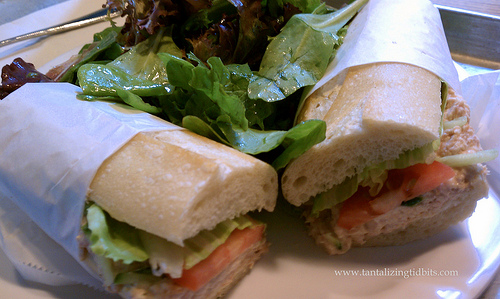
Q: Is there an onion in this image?
A: Yes, there is an onion.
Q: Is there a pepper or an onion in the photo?
A: Yes, there is an onion.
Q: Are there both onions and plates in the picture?
A: Yes, there are both an onion and a plate.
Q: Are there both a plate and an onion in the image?
A: Yes, there are both an onion and a plate.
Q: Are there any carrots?
A: No, there are no carrots.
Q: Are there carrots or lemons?
A: No, there are no carrots or lemons.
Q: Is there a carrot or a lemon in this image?
A: No, there are no carrots or lemons.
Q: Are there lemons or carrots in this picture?
A: No, there are no carrots or lemons.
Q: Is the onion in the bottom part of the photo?
A: Yes, the onion is in the bottom of the image.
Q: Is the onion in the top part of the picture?
A: No, the onion is in the bottom of the image.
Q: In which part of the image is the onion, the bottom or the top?
A: The onion is in the bottom of the image.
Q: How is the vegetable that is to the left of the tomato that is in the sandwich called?
A: The vegetable is an onion.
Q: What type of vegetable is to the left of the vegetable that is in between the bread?
A: The vegetable is an onion.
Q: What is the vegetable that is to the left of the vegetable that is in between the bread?
A: The vegetable is an onion.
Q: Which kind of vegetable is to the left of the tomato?
A: The vegetable is an onion.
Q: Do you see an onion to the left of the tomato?
A: Yes, there is an onion to the left of the tomato.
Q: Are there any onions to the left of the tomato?
A: Yes, there is an onion to the left of the tomato.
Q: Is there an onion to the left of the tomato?
A: Yes, there is an onion to the left of the tomato.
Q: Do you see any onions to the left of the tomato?
A: Yes, there is an onion to the left of the tomato.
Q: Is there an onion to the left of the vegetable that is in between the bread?
A: Yes, there is an onion to the left of the tomato.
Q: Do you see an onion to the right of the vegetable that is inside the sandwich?
A: No, the onion is to the left of the tomato.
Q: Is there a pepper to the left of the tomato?
A: No, there is an onion to the left of the tomato.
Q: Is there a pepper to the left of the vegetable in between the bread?
A: No, there is an onion to the left of the tomato.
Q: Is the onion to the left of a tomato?
A: Yes, the onion is to the left of a tomato.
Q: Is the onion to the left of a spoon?
A: No, the onion is to the left of a tomato.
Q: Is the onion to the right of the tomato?
A: No, the onion is to the left of the tomato.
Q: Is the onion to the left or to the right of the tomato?
A: The onion is to the left of the tomato.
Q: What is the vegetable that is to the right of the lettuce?
A: The vegetable is an onion.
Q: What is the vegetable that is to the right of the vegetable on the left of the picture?
A: The vegetable is an onion.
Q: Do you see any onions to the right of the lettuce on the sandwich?
A: Yes, there is an onion to the right of the lettuce.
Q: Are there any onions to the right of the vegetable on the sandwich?
A: Yes, there is an onion to the right of the lettuce.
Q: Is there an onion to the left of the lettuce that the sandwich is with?
A: No, the onion is to the right of the lettuce.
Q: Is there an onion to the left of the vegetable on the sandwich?
A: No, the onion is to the right of the lettuce.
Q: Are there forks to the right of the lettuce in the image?
A: No, there is an onion to the right of the lettuce.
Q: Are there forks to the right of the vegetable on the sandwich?
A: No, there is an onion to the right of the lettuce.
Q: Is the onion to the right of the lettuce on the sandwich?
A: Yes, the onion is to the right of the lettuce.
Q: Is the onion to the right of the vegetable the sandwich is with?
A: Yes, the onion is to the right of the lettuce.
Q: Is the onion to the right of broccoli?
A: No, the onion is to the right of the lettuce.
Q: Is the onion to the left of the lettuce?
A: No, the onion is to the right of the lettuce.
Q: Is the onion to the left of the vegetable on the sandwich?
A: No, the onion is to the right of the lettuce.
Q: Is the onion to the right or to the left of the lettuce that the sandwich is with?
A: The onion is to the right of the lettuce.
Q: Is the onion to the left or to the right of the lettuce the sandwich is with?
A: The onion is to the right of the lettuce.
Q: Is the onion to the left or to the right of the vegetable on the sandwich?
A: The onion is to the right of the lettuce.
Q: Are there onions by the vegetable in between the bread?
A: Yes, there is an onion by the tomato.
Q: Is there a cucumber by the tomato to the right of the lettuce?
A: No, there is an onion by the tomato.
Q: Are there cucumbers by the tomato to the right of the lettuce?
A: No, there is an onion by the tomato.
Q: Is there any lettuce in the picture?
A: Yes, there is lettuce.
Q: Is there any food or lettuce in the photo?
A: Yes, there is lettuce.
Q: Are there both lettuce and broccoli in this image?
A: No, there is lettuce but no broccoli.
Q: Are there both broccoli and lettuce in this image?
A: No, there is lettuce but no broccoli.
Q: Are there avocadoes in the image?
A: No, there are no avocadoes.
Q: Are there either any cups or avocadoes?
A: No, there are no avocadoes or cups.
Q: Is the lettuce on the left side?
A: Yes, the lettuce is on the left of the image.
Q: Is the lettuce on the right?
A: No, the lettuce is on the left of the image.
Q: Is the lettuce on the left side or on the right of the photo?
A: The lettuce is on the left of the image.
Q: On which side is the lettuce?
A: The lettuce is on the left of the image.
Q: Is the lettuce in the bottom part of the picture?
A: Yes, the lettuce is in the bottom of the image.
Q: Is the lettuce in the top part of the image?
A: No, the lettuce is in the bottom of the image.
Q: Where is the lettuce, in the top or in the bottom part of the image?
A: The lettuce is in the bottom of the image.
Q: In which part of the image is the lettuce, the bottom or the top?
A: The lettuce is in the bottom of the image.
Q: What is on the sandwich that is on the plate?
A: The lettuce is on the sandwich.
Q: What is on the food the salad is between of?
A: The lettuce is on the sandwich.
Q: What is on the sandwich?
A: The lettuce is on the sandwich.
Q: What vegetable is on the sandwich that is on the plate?
A: The vegetable is lettuce.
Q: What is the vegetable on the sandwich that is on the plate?
A: The vegetable is lettuce.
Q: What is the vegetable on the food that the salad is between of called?
A: The vegetable is lettuce.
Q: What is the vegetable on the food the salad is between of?
A: The vegetable is lettuce.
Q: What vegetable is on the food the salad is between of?
A: The vegetable is lettuce.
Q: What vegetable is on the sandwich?
A: The vegetable is lettuce.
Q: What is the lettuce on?
A: The lettuce is on the sandwich.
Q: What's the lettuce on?
A: The lettuce is on the sandwich.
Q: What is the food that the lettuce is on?
A: The food is a sandwich.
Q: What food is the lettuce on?
A: The lettuce is on the sandwich.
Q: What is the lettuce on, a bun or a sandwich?
A: The lettuce is on a sandwich.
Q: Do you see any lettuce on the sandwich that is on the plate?
A: Yes, there is lettuce on the sandwich.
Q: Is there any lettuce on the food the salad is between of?
A: Yes, there is lettuce on the sandwich.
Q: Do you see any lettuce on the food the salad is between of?
A: Yes, there is lettuce on the sandwich.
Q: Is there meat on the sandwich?
A: No, there is lettuce on the sandwich.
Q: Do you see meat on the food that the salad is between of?
A: No, there is lettuce on the sandwich.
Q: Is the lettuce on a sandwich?
A: Yes, the lettuce is on a sandwich.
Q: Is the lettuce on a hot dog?
A: No, the lettuce is on a sandwich.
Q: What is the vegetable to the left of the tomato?
A: The vegetable is lettuce.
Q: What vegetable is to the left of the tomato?
A: The vegetable is lettuce.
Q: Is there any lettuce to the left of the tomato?
A: Yes, there is lettuce to the left of the tomato.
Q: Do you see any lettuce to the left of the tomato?
A: Yes, there is lettuce to the left of the tomato.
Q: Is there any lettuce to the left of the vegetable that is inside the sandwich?
A: Yes, there is lettuce to the left of the tomato.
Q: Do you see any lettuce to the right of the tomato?
A: No, the lettuce is to the left of the tomato.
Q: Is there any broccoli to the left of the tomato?
A: No, there is lettuce to the left of the tomato.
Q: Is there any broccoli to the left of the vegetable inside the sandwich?
A: No, there is lettuce to the left of the tomato.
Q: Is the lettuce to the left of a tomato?
A: Yes, the lettuce is to the left of a tomato.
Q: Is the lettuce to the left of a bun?
A: No, the lettuce is to the left of a tomato.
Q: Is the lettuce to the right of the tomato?
A: No, the lettuce is to the left of the tomato.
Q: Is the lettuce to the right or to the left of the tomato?
A: The lettuce is to the left of the tomato.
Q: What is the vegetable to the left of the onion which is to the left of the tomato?
A: The vegetable is lettuce.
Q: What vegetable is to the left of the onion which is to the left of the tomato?
A: The vegetable is lettuce.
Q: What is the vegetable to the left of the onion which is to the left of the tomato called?
A: The vegetable is lettuce.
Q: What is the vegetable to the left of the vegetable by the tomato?
A: The vegetable is lettuce.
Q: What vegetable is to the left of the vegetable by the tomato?
A: The vegetable is lettuce.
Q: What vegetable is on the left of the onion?
A: The vegetable is lettuce.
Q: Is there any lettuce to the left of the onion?
A: Yes, there is lettuce to the left of the onion.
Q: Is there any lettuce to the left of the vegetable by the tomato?
A: Yes, there is lettuce to the left of the onion.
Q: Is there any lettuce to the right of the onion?
A: No, the lettuce is to the left of the onion.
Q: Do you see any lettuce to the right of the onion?
A: No, the lettuce is to the left of the onion.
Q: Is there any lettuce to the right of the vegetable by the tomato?
A: No, the lettuce is to the left of the onion.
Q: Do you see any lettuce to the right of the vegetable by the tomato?
A: No, the lettuce is to the left of the onion.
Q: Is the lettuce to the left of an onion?
A: Yes, the lettuce is to the left of an onion.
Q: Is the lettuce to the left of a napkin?
A: No, the lettuce is to the left of an onion.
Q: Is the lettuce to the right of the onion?
A: No, the lettuce is to the left of the onion.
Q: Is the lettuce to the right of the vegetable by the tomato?
A: No, the lettuce is to the left of the onion.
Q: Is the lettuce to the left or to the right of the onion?
A: The lettuce is to the left of the onion.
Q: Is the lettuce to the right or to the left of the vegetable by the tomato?
A: The lettuce is to the left of the onion.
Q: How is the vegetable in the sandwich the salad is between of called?
A: The vegetable is lettuce.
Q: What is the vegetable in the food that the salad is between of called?
A: The vegetable is lettuce.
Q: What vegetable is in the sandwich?
A: The vegetable is lettuce.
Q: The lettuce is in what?
A: The lettuce is in the sandwich.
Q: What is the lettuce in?
A: The lettuce is in the sandwich.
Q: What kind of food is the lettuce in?
A: The lettuce is in the sandwich.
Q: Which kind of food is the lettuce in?
A: The lettuce is in the sandwich.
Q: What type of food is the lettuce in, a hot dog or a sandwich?
A: The lettuce is in a sandwich.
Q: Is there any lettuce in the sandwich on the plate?
A: Yes, there is lettuce in the sandwich.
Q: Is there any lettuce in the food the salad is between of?
A: Yes, there is lettuce in the sandwich.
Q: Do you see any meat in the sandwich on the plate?
A: No, there is lettuce in the sandwich.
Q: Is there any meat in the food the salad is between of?
A: No, there is lettuce in the sandwich.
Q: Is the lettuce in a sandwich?
A: Yes, the lettuce is in a sandwich.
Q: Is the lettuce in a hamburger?
A: No, the lettuce is in a sandwich.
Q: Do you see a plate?
A: Yes, there is a plate.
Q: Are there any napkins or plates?
A: Yes, there is a plate.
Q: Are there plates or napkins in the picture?
A: Yes, there is a plate.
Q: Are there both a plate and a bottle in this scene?
A: No, there is a plate but no bottles.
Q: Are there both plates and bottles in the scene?
A: No, there is a plate but no bottles.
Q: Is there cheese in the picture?
A: No, there is no cheese.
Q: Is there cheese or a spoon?
A: No, there are no cheese or spoons.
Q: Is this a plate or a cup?
A: This is a plate.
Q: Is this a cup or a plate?
A: This is a plate.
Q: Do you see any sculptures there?
A: No, there are no sculptures.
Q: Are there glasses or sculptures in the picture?
A: No, there are no sculptures or glasses.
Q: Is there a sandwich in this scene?
A: Yes, there is a sandwich.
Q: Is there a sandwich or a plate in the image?
A: Yes, there is a sandwich.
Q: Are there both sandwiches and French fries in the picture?
A: No, there is a sandwich but no fries.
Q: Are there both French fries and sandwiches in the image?
A: No, there is a sandwich but no fries.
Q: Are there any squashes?
A: No, there are no squashes.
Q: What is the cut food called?
A: The food is a sandwich.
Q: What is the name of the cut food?
A: The food is a sandwich.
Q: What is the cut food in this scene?
A: The food is a sandwich.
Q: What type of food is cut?
A: The food is a sandwich.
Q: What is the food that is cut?
A: The food is a sandwich.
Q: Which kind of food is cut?
A: The food is a sandwich.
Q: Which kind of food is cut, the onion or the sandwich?
A: The sandwich is cut.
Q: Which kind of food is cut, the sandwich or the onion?
A: The sandwich is cut.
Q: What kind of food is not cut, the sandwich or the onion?
A: The onion is not cut.